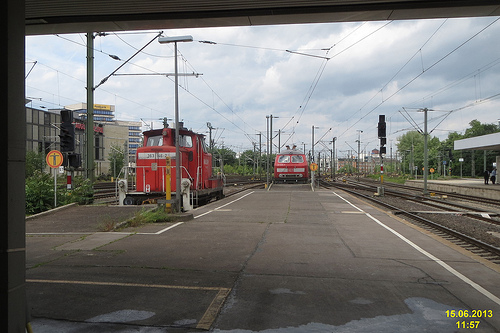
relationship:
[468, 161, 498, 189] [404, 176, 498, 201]
people standing on platform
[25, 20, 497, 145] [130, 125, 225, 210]
lines running above train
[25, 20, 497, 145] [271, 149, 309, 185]
lines running above train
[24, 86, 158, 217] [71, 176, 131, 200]
buildings next to train tracks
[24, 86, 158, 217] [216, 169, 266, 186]
buildings next to train tracks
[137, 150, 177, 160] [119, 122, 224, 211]
number on front of train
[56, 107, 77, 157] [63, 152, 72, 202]
lights on pole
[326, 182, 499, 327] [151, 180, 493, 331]
white lines on edge of plateform